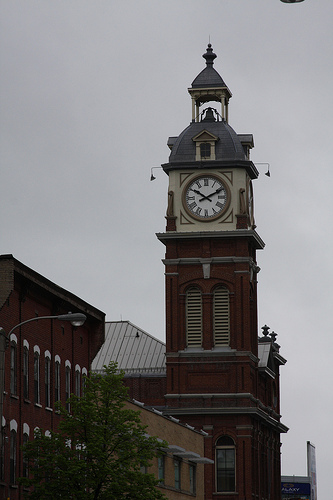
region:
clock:
[176, 173, 234, 232]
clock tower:
[164, 35, 251, 379]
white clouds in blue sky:
[58, 36, 88, 54]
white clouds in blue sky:
[74, 162, 109, 202]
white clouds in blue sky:
[292, 169, 331, 206]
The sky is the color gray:
[22, 12, 136, 252]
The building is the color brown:
[174, 238, 256, 412]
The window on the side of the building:
[207, 428, 238, 497]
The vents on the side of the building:
[180, 282, 235, 351]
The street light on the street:
[10, 307, 92, 341]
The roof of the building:
[91, 316, 170, 379]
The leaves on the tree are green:
[47, 407, 137, 492]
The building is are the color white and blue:
[278, 440, 327, 498]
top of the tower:
[194, 31, 231, 70]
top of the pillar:
[181, 40, 243, 76]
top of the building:
[183, 50, 271, 124]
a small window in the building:
[199, 434, 260, 497]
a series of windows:
[1, 405, 221, 498]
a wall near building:
[300, 431, 325, 499]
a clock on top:
[166, 159, 256, 222]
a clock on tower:
[175, 174, 258, 227]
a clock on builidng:
[183, 170, 228, 211]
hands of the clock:
[194, 188, 221, 205]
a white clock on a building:
[175, 167, 239, 245]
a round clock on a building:
[168, 155, 257, 226]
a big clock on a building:
[171, 140, 269, 226]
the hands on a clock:
[185, 170, 242, 215]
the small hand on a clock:
[182, 182, 213, 206]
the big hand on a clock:
[188, 176, 241, 219]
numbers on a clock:
[179, 162, 249, 228]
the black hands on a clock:
[176, 163, 242, 232]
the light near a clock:
[48, 296, 112, 358]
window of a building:
[208, 439, 241, 491]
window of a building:
[186, 456, 208, 486]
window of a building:
[173, 460, 190, 490]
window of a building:
[154, 454, 173, 484]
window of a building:
[4, 343, 24, 397]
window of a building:
[31, 350, 50, 404]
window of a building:
[47, 361, 71, 404]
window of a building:
[62, 370, 91, 414]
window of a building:
[6, 435, 28, 464]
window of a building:
[7, 457, 26, 484]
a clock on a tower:
[181, 171, 232, 222]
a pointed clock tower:
[149, 32, 270, 424]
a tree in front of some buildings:
[21, 358, 170, 499]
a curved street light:
[2, 312, 89, 496]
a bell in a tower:
[202, 108, 219, 125]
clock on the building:
[151, 158, 248, 234]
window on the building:
[203, 431, 252, 499]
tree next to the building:
[28, 366, 194, 498]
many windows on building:
[107, 442, 222, 497]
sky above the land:
[279, 377, 324, 433]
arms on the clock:
[179, 170, 239, 213]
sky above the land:
[26, 82, 143, 193]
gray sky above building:
[0, 81, 123, 200]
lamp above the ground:
[39, 302, 97, 339]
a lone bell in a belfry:
[199, 105, 221, 122]